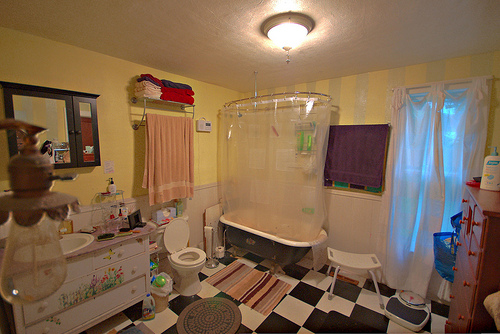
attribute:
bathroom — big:
[14, 33, 466, 332]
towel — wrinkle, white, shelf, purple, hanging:
[159, 137, 206, 170]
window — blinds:
[373, 109, 463, 194]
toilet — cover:
[158, 210, 213, 273]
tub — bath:
[194, 167, 361, 281]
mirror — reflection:
[21, 72, 96, 164]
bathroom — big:
[53, 44, 472, 334]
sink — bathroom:
[56, 214, 119, 278]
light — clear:
[278, 25, 307, 55]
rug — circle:
[202, 270, 273, 331]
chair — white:
[316, 245, 379, 305]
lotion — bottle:
[92, 199, 140, 255]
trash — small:
[140, 271, 181, 316]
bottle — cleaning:
[83, 168, 130, 243]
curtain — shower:
[219, 98, 308, 230]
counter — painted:
[91, 222, 139, 286]